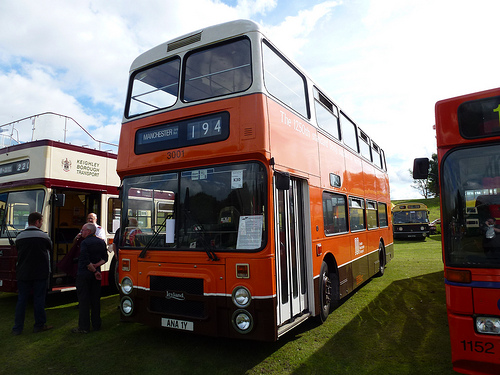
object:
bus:
[116, 19, 394, 341]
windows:
[321, 188, 350, 237]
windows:
[260, 36, 312, 121]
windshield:
[118, 161, 267, 251]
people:
[54, 210, 109, 281]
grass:
[275, 231, 444, 374]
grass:
[2, 298, 283, 373]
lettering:
[279, 111, 312, 139]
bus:
[391, 202, 432, 241]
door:
[273, 169, 314, 328]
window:
[181, 35, 253, 103]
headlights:
[230, 306, 253, 333]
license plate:
[161, 316, 194, 331]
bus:
[433, 86, 499, 374]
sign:
[137, 125, 180, 145]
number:
[186, 117, 222, 140]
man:
[76, 222, 109, 334]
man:
[15, 212, 55, 335]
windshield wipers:
[138, 213, 176, 263]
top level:
[115, 17, 392, 194]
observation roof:
[1, 109, 122, 157]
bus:
[0, 111, 121, 299]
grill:
[150, 274, 202, 316]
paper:
[235, 213, 264, 249]